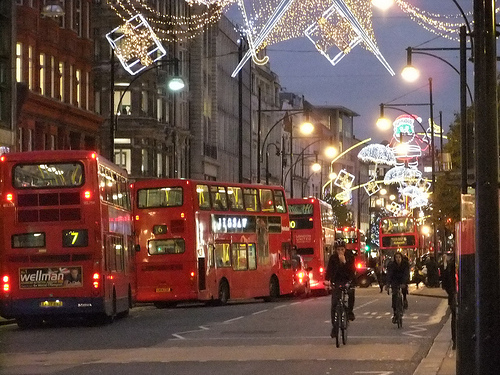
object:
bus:
[0, 148, 142, 330]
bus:
[130, 177, 297, 310]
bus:
[287, 194, 338, 294]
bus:
[378, 215, 425, 272]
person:
[323, 238, 359, 340]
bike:
[323, 280, 354, 345]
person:
[378, 250, 416, 324]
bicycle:
[382, 284, 410, 332]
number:
[66, 229, 79, 246]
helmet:
[333, 236, 346, 248]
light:
[397, 61, 425, 84]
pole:
[456, 26, 470, 194]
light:
[374, 115, 396, 133]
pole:
[427, 76, 437, 198]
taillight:
[92, 271, 101, 281]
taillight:
[2, 270, 11, 282]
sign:
[13, 265, 67, 286]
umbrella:
[356, 142, 399, 165]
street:
[3, 280, 456, 375]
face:
[394, 121, 413, 137]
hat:
[388, 113, 422, 129]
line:
[223, 314, 245, 325]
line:
[251, 305, 270, 318]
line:
[274, 301, 286, 313]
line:
[289, 297, 305, 307]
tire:
[333, 306, 341, 348]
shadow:
[0, 304, 210, 352]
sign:
[378, 232, 415, 250]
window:
[231, 242, 249, 272]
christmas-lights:
[100, 0, 473, 78]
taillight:
[190, 269, 196, 280]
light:
[194, 186, 206, 196]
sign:
[206, 213, 284, 230]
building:
[2, 1, 105, 153]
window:
[215, 243, 233, 269]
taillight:
[319, 266, 325, 277]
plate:
[40, 297, 65, 307]